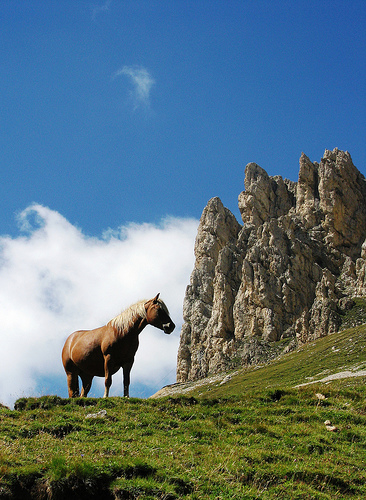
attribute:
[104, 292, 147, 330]
hair — white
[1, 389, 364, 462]
field — grassy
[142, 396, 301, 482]
grass — green, bright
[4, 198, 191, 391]
clouds — white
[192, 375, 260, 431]
grasses — green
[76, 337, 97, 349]
coat — brown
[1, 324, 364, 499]
grass patch — green, bright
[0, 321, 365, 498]
grass — bright, green, short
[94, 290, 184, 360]
horse — standing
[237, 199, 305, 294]
hills — grey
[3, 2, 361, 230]
sky — blue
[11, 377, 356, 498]
grass — bright, green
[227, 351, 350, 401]
green grass — bright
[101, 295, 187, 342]
blonde hair — long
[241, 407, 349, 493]
grass patch — green, bright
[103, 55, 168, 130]
cloud — small, white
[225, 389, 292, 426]
grass — green, bright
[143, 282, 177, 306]
ear — brown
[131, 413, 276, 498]
grass — green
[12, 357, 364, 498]
field — open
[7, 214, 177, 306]
cloud — white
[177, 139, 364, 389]
stone — grey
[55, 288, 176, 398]
horse — brown, looking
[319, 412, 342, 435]
rock — small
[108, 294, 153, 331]
mane — blonde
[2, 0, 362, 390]
sky — blue